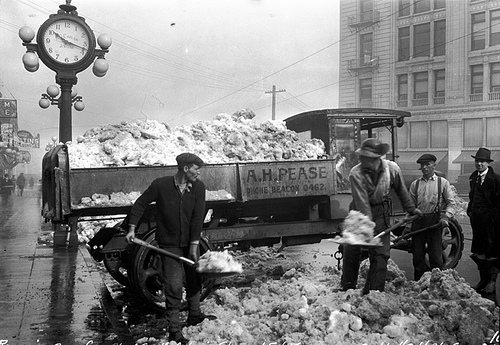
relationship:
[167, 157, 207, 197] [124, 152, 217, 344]
head of a man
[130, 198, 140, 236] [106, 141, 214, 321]
arm of a person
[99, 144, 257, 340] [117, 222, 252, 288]
man has shovel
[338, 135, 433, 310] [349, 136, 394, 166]
man has hat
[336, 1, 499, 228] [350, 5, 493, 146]
building has windows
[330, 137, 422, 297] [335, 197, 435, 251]
man has shovel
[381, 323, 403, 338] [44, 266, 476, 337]
rock on ground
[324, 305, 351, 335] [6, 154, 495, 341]
rock on ground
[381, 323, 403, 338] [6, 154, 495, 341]
rock on ground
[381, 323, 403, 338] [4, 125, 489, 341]
rock on ground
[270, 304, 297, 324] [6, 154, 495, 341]
rock on ground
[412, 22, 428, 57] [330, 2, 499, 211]
window on a building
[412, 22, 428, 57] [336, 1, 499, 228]
window on a building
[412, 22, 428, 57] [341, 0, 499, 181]
window on a building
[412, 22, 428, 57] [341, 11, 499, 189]
window on a building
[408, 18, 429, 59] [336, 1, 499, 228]
window on a building